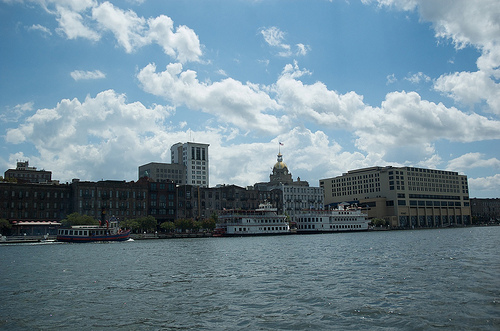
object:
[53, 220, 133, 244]
boat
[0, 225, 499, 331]
water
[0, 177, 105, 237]
building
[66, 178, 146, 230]
building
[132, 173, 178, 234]
building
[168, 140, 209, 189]
building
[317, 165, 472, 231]
building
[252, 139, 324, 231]
building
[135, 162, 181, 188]
building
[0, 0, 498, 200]
sky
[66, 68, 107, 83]
clouds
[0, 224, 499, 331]
ripple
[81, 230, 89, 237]
window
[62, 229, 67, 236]
window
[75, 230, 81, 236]
window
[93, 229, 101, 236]
window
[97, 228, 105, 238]
window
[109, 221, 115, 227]
window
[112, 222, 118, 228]
window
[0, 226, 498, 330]
wave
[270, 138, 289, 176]
dome